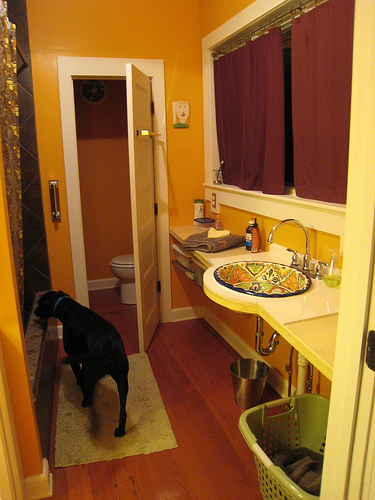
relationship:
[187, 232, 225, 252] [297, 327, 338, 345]
towel on top of cabinet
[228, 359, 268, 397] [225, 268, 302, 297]
bucket under sink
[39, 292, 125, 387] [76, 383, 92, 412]
dog has a leg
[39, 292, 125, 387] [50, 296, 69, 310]
dog wearing a collar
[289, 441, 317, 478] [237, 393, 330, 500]
clothes in waste basket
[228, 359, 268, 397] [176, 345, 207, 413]
waste basket sitting on floor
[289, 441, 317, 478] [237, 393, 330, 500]
clothes are in waste basket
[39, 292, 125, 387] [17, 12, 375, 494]
dog standing in bathroom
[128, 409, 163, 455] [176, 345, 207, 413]
rug on floor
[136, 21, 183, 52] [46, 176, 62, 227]
wall has a towel holder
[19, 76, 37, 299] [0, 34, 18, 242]
shower has curtain